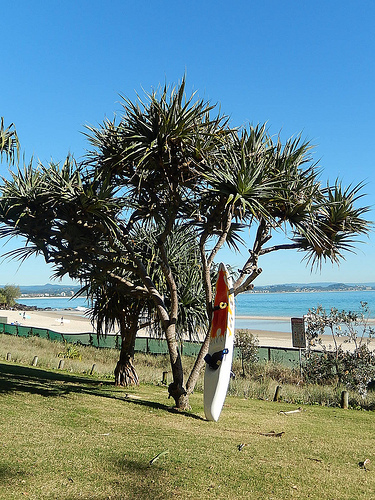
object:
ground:
[0, 303, 374, 498]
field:
[0, 331, 374, 497]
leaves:
[0, 118, 23, 172]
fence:
[0, 323, 343, 376]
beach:
[0, 308, 374, 353]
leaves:
[145, 103, 189, 157]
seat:
[203, 347, 230, 371]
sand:
[0, 308, 375, 357]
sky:
[0, 0, 375, 288]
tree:
[0, 71, 375, 412]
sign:
[290, 316, 307, 349]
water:
[10, 292, 375, 340]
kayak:
[203, 261, 236, 423]